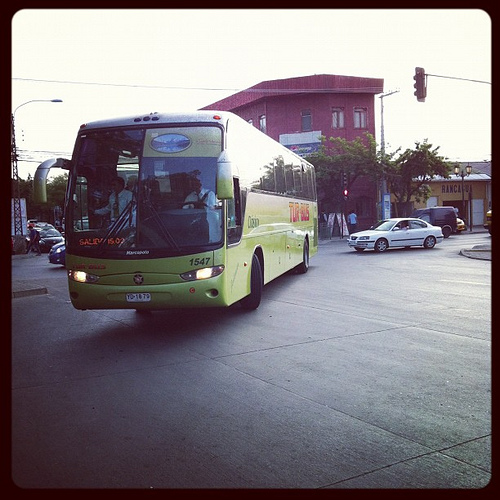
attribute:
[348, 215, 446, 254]
car — white, small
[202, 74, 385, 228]
building — red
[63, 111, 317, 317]
bus — green, large, turning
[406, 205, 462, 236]
suv — dark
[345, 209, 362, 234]
man — walking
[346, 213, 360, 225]
shirt — blue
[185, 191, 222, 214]
shirt — white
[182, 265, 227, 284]
headlight — illuminated, on, in front, yellow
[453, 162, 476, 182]
light — two in count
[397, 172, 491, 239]
building — yellow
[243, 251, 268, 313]
tire — black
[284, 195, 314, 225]
letters — orange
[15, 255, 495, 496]
road — smooth